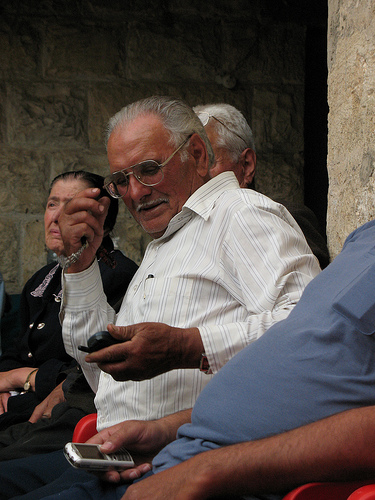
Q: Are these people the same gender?
A: No, they are both male and female.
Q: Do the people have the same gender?
A: No, they are both male and female.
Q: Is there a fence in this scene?
A: No, there are no fences.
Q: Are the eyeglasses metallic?
A: Yes, the eyeglasses are metallic.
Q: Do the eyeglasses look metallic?
A: Yes, the eyeglasses are metallic.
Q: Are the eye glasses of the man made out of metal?
A: Yes, the eyeglasses are made of metal.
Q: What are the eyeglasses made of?
A: The eyeglasses are made of metal.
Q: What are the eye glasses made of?
A: The eyeglasses are made of metal.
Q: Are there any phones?
A: Yes, there is a phone.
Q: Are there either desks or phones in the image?
A: Yes, there is a phone.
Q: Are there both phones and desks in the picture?
A: No, there is a phone but no desks.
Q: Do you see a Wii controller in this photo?
A: No, there are no Wii controllers.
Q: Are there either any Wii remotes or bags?
A: No, there are no Wii remotes or bags.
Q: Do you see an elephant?
A: No, there are no elephants.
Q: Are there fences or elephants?
A: No, there are no elephants or fences.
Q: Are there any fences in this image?
A: No, there are no fences.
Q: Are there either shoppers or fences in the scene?
A: No, there are no fences or shoppers.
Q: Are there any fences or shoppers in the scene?
A: No, there are no fences or shoppers.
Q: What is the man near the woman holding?
A: The man is holding the phone.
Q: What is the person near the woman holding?
A: The man is holding the phone.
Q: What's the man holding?
A: The man is holding the phone.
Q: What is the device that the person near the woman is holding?
A: The device is a phone.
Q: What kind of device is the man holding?
A: The man is holding the phone.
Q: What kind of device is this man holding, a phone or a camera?
A: The man is holding a phone.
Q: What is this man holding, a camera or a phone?
A: The man is holding a phone.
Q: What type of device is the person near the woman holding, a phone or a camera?
A: The man is holding a phone.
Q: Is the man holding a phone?
A: Yes, the man is holding a phone.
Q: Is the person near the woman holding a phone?
A: Yes, the man is holding a phone.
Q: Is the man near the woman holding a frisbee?
A: No, the man is holding a phone.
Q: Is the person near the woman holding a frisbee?
A: No, the man is holding a phone.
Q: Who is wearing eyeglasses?
A: The man is wearing eyeglasses.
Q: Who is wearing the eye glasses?
A: The man is wearing eyeglasses.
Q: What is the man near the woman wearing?
A: The man is wearing eye glasses.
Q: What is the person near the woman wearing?
A: The man is wearing eye glasses.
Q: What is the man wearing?
A: The man is wearing eye glasses.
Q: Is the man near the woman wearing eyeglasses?
A: Yes, the man is wearing eyeglasses.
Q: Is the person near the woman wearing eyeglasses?
A: Yes, the man is wearing eyeglasses.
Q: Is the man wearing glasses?
A: No, the man is wearing eyeglasses.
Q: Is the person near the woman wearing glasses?
A: No, the man is wearing eyeglasses.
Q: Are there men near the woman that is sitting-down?
A: Yes, there is a man near the woman.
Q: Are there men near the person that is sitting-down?
A: Yes, there is a man near the woman.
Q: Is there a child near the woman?
A: No, there is a man near the woman.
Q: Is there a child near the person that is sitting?
A: No, there is a man near the woman.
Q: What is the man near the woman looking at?
A: The man is looking at the phone.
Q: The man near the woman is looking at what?
A: The man is looking at the phone.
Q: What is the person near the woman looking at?
A: The man is looking at the phone.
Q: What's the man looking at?
A: The man is looking at the phone.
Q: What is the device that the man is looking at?
A: The device is a phone.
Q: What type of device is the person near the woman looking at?
A: The man is looking at the phone.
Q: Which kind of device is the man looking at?
A: The man is looking at the phone.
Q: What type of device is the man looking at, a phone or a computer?
A: The man is looking at a phone.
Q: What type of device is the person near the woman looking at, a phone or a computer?
A: The man is looking at a phone.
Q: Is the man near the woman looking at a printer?
A: No, the man is looking at the phone.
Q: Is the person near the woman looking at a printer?
A: No, the man is looking at the phone.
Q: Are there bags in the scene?
A: No, there are no bags.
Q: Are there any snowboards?
A: No, there are no snowboards.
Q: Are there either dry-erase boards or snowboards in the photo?
A: No, there are no snowboards or dry-erase boards.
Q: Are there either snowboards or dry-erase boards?
A: No, there are no snowboards or dry-erase boards.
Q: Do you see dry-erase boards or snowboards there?
A: No, there are no snowboards or dry-erase boards.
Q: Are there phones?
A: Yes, there is a phone.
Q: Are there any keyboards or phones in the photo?
A: Yes, there is a phone.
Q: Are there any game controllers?
A: No, there are no game controllers.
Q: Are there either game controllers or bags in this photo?
A: No, there are no game controllers or bags.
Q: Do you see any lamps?
A: No, there are no lamps.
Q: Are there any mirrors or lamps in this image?
A: No, there are no lamps or mirrors.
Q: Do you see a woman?
A: Yes, there is a woman.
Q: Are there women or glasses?
A: Yes, there is a woman.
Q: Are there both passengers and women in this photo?
A: No, there is a woman but no passengers.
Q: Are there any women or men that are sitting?
A: Yes, the woman is sitting.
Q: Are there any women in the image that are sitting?
A: Yes, there is a woman that is sitting.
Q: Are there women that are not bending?
A: Yes, there is a woman that is sitting.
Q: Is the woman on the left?
A: Yes, the woman is on the left of the image.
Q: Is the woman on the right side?
A: No, the woman is on the left of the image.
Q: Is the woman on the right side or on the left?
A: The woman is on the left of the image.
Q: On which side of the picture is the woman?
A: The woman is on the left of the image.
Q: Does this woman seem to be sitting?
A: Yes, the woman is sitting.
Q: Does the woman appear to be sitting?
A: Yes, the woman is sitting.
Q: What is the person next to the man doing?
A: The woman is sitting.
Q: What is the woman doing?
A: The woman is sitting.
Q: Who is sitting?
A: The woman is sitting.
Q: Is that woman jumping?
A: No, the woman is sitting.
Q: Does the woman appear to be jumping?
A: No, the woman is sitting.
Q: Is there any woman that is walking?
A: No, there is a woman but she is sitting.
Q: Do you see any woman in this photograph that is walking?
A: No, there is a woman but she is sitting.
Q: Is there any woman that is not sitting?
A: No, there is a woman but she is sitting.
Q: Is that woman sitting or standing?
A: The woman is sitting.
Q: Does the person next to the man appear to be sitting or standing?
A: The woman is sitting.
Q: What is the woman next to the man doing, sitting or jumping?
A: The woman is sitting.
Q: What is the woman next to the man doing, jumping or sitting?
A: The woman is sitting.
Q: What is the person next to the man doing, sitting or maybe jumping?
A: The woman is sitting.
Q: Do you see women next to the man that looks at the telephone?
A: Yes, there is a woman next to the man.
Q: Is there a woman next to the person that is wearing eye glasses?
A: Yes, there is a woman next to the man.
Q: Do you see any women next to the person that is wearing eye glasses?
A: Yes, there is a woman next to the man.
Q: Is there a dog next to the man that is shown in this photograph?
A: No, there is a woman next to the man.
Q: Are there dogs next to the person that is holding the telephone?
A: No, there is a woman next to the man.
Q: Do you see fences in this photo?
A: No, there are no fences.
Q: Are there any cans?
A: No, there are no cans.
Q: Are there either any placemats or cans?
A: No, there are no cans or placemats.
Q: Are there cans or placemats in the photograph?
A: No, there are no cans or placemats.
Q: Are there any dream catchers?
A: No, there are no dream catchers.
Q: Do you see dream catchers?
A: No, there are no dream catchers.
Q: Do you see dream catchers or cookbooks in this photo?
A: No, there are no dream catchers or cookbooks.